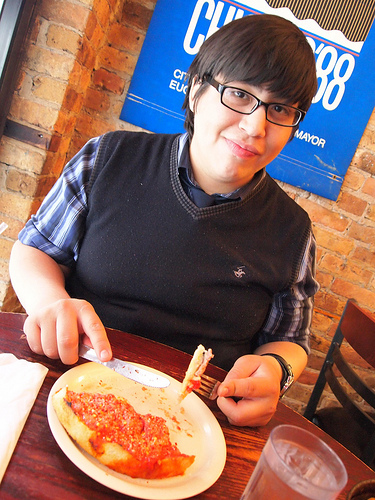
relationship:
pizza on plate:
[70, 379, 202, 480] [45, 338, 237, 499]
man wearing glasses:
[6, 10, 327, 431] [203, 73, 311, 133]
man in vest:
[6, 10, 327, 431] [84, 113, 310, 392]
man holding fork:
[6, 10, 327, 431] [193, 369, 238, 406]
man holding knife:
[6, 10, 327, 431] [35, 321, 177, 398]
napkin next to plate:
[0, 338, 54, 500] [45, 338, 237, 499]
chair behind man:
[304, 290, 375, 465] [6, 10, 327, 431]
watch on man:
[256, 348, 299, 406] [6, 10, 327, 431]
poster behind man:
[113, 1, 373, 210] [6, 10, 327, 431]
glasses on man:
[203, 73, 311, 133] [6, 10, 327, 431]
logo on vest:
[226, 260, 247, 283] [84, 113, 310, 392]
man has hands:
[6, 10, 327, 431] [18, 295, 289, 437]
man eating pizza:
[6, 10, 327, 431] [70, 379, 202, 480]